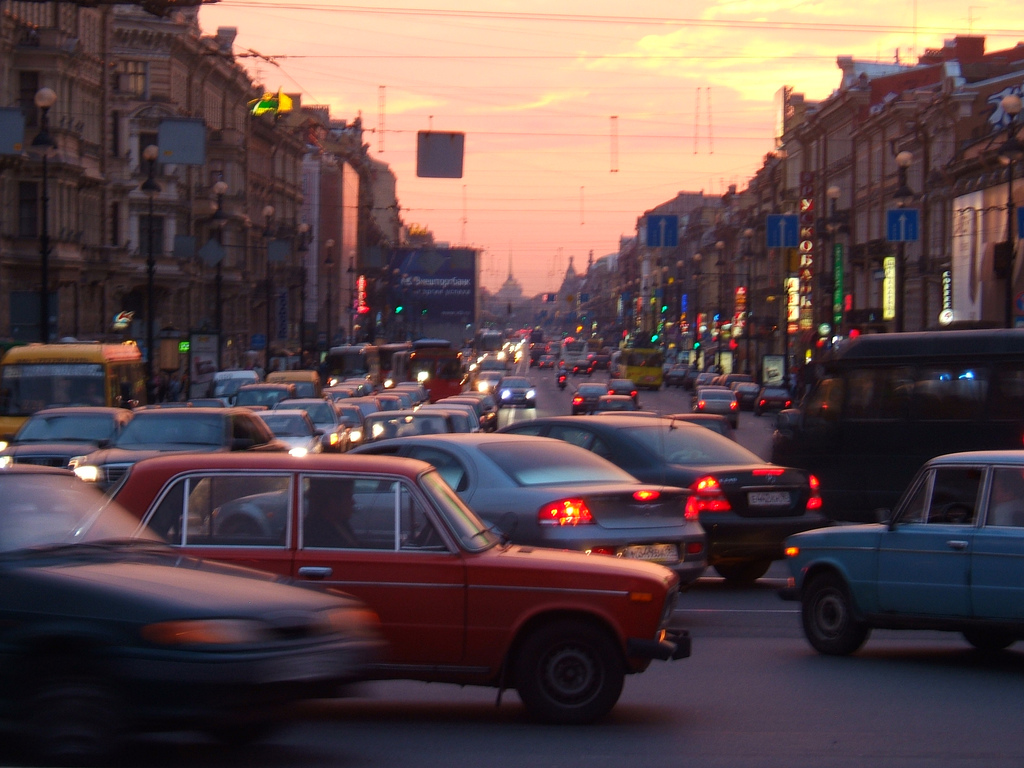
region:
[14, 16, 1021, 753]
a scene happening during the sunset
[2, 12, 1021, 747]
a scene outside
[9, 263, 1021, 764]
vehicles on the road moving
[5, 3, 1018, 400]
rows of buildings in the background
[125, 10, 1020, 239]
power lines in the air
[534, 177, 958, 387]
lights in the area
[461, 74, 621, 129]
a white cloud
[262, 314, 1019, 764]
gray road in center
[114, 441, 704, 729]
the car is red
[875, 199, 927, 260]
the banner is blue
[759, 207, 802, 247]
the banner is blue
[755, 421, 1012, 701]
the car is blue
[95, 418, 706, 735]
a red four door sedan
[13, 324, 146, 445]
a yellow truck is parked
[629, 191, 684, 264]
a small blue banner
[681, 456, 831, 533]
the taillights are red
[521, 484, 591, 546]
the taillight is red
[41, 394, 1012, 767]
the cars are on the road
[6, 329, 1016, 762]
heavy traffic on the road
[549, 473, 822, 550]
the tail light is on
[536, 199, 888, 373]
the stores have lights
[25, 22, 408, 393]
the buildings are in a row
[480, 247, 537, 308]
a building in the distance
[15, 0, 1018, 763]
the scene takes place outdoors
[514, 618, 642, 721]
tire on a car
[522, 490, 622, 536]
tail light on a car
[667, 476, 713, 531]
tail light on a car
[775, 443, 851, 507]
tail light on a car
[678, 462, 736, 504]
tail light on a car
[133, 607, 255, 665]
light on a car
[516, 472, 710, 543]
Rear car lights are turned on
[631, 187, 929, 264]
Arrows on three blue signs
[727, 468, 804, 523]
A white license plate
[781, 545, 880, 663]
A black rubber car tire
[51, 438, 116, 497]
A headlight is turned on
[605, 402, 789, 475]
Back window of a car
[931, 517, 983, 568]
Handle of a car door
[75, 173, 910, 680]
cars on the street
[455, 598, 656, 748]
front tire of the car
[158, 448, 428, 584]
side windows of the car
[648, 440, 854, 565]
back lights on car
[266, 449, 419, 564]
person in the car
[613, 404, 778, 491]
back window of car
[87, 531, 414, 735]
front part of a car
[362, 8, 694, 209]
wires above the land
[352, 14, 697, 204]
sky above the land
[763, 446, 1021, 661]
the side of a blue car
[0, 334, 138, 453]
the front of a yellow van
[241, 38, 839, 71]
a long electrical power line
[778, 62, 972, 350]
a tall brown building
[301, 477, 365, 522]
the head of a person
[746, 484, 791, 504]
a white license plate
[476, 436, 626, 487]
black mirror colored window tint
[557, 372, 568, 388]
the back of a motorcycle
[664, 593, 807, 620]
a long white line